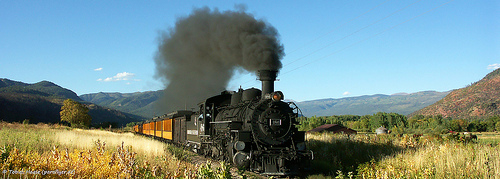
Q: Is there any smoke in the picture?
A: Yes, there is smoke.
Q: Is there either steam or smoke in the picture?
A: Yes, there is smoke.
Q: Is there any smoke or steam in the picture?
A: Yes, there is smoke.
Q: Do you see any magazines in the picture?
A: No, there are no magazines.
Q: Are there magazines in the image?
A: No, there are no magazines.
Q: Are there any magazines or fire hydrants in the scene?
A: No, there are no magazines or fire hydrants.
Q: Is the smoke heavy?
A: Yes, the smoke is heavy.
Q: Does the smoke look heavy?
A: Yes, the smoke is heavy.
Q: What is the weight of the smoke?
A: The smoke is heavy.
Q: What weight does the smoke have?
A: The smoke has heavy weight.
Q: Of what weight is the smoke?
A: The smoke is heavy.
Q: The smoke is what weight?
A: The smoke is heavy.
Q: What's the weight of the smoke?
A: The smoke is heavy.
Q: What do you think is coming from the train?
A: The smoke is coming from the train.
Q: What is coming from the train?
A: The smoke is coming from the train.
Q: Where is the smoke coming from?
A: The smoke is coming from the train.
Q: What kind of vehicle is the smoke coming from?
A: The smoke is coming from the train.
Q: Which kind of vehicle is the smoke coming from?
A: The smoke is coming from the train.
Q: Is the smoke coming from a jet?
A: No, the smoke is coming from the train.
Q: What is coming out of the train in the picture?
A: The smoke is coming out of the train.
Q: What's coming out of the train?
A: The smoke is coming out of the train.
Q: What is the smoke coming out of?
A: The smoke is coming out of the train.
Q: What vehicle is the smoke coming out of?
A: The smoke is coming out of the train.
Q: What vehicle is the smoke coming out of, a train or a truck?
A: The smoke is coming out of a train.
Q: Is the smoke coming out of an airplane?
A: No, the smoke is coming out of a train.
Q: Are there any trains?
A: Yes, there is a train.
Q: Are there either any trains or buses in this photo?
A: Yes, there is a train.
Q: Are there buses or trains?
A: Yes, there is a train.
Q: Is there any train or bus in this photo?
A: Yes, there is a train.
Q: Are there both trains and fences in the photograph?
A: No, there is a train but no fences.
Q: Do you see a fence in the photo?
A: No, there are no fences.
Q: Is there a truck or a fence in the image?
A: No, there are no fences or trucks.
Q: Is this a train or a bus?
A: This is a train.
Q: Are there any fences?
A: No, there are no fences.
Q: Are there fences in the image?
A: No, there are no fences.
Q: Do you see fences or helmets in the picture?
A: No, there are no fences or helmets.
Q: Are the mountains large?
A: Yes, the mountains are large.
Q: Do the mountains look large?
A: Yes, the mountains are large.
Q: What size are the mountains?
A: The mountains are large.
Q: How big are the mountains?
A: The mountains are large.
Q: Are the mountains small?
A: No, the mountains are large.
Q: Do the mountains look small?
A: No, the mountains are large.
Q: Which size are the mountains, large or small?
A: The mountains are large.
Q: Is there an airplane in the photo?
A: No, there are no airplanes.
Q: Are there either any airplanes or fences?
A: No, there are no airplanes or fences.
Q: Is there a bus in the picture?
A: No, there are no buses.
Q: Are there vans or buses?
A: No, there are no buses or vans.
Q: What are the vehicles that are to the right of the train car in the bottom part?
A: The vehicles are cars.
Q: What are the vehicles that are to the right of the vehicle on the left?
A: The vehicles are cars.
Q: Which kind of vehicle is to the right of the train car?
A: The vehicles are cars.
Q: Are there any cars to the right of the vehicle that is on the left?
A: Yes, there are cars to the right of the train car.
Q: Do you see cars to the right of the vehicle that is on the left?
A: Yes, there are cars to the right of the train car.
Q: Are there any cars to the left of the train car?
A: No, the cars are to the right of the train car.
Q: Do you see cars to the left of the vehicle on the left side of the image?
A: No, the cars are to the right of the train car.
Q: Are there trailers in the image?
A: No, there are no trailers.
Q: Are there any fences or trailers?
A: No, there are no trailers or fences.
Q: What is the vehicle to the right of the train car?
A: The vehicle is a car.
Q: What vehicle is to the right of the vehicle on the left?
A: The vehicle is a car.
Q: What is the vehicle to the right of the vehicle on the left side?
A: The vehicle is a car.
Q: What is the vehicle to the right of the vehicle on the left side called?
A: The vehicle is a car.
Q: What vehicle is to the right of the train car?
A: The vehicle is a car.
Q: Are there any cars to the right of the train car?
A: Yes, there is a car to the right of the train car.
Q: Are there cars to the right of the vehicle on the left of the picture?
A: Yes, there is a car to the right of the train car.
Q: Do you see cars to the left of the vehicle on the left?
A: No, the car is to the right of the train car.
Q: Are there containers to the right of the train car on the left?
A: No, there is a car to the right of the train car.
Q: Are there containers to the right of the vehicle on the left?
A: No, there is a car to the right of the train car.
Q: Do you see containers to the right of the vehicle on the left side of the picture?
A: No, there is a car to the right of the train car.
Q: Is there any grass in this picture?
A: Yes, there is grass.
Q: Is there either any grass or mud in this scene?
A: Yes, there is grass.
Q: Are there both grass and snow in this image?
A: No, there is grass but no snow.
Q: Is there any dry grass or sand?
A: Yes, there is dry grass.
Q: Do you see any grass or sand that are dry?
A: Yes, the grass is dry.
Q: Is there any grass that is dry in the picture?
A: Yes, there is dry grass.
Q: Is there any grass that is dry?
A: Yes, there is grass that is dry.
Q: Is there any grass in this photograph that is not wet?
A: Yes, there is dry grass.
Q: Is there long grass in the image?
A: Yes, there is long grass.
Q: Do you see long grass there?
A: Yes, there is long grass.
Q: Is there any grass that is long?
A: Yes, there is grass that is long.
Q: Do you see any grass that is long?
A: Yes, there is grass that is long.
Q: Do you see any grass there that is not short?
A: Yes, there is long grass.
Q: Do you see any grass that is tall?
A: Yes, there is tall grass.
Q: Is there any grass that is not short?
A: Yes, there is tall grass.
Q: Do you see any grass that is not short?
A: Yes, there is tall grass.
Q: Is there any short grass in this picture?
A: Yes, there is short grass.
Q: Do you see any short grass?
A: Yes, there is short grass.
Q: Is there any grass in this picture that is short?
A: Yes, there is grass that is short.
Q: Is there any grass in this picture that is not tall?
A: Yes, there is short grass.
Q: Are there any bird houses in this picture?
A: No, there are no bird houses.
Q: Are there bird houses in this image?
A: No, there are no bird houses.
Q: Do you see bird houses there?
A: No, there are no bird houses.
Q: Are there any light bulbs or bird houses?
A: No, there are no bird houses or light bulbs.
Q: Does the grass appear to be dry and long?
A: Yes, the grass is dry and long.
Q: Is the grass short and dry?
A: No, the grass is dry but long.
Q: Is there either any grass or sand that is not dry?
A: No, there is grass but it is dry.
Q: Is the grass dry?
A: Yes, the grass is dry.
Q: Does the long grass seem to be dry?
A: Yes, the grass is dry.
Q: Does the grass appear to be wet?
A: No, the grass is dry.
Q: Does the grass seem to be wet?
A: No, the grass is dry.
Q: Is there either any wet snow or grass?
A: No, there is grass but it is dry.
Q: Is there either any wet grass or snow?
A: No, there is grass but it is dry.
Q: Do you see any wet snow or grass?
A: No, there is grass but it is dry.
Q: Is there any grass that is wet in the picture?
A: No, there is grass but it is dry.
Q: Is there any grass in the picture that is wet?
A: No, there is grass but it is dry.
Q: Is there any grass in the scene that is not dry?
A: No, there is grass but it is dry.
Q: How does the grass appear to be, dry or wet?
A: The grass is dry.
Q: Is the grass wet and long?
A: No, the grass is long but dry.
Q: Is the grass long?
A: Yes, the grass is long.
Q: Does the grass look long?
A: Yes, the grass is long.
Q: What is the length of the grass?
A: The grass is long.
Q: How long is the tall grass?
A: The grass is long.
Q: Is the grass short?
A: No, the grass is long.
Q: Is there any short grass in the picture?
A: No, there is grass but it is long.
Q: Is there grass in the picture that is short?
A: No, there is grass but it is long.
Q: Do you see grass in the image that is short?
A: No, there is grass but it is long.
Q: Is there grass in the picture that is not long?
A: No, there is grass but it is long.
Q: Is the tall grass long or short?
A: The grass is long.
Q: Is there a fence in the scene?
A: No, there are no fences.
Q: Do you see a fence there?
A: No, there are no fences.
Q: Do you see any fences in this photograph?
A: No, there are no fences.